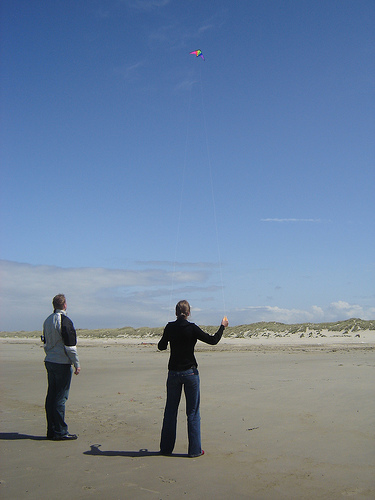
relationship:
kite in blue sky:
[190, 48, 207, 63] [0, 0, 375, 328]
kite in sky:
[189, 49, 205, 62] [105, 70, 221, 176]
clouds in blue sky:
[0, 258, 373, 332] [0, 0, 375, 328]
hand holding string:
[214, 313, 233, 329] [193, 68, 253, 242]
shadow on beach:
[83, 441, 163, 459] [1, 337, 373, 497]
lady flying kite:
[155, 296, 231, 459] [191, 41, 208, 59]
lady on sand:
[155, 296, 231, 459] [254, 362, 350, 462]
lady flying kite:
[155, 296, 231, 459] [185, 40, 206, 67]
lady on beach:
[155, 296, 231, 459] [1, 337, 373, 497]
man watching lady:
[40, 294, 81, 439] [155, 296, 231, 459]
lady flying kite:
[155, 296, 231, 459] [187, 46, 207, 64]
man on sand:
[40, 294, 81, 439] [1, 332, 372, 499]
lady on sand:
[155, 296, 231, 459] [1, 332, 372, 499]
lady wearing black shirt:
[158, 300, 229, 456] [153, 320, 225, 370]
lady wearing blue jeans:
[158, 300, 229, 456] [158, 368, 203, 456]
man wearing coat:
[34, 289, 80, 442] [38, 311, 81, 367]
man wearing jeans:
[34, 289, 80, 442] [40, 363, 73, 441]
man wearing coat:
[40, 294, 81, 439] [39, 307, 80, 366]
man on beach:
[40, 294, 81, 439] [1, 337, 373, 497]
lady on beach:
[158, 300, 229, 456] [1, 337, 373, 497]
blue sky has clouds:
[0, 0, 375, 328] [0, 253, 373, 323]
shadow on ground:
[83, 444, 188, 457] [2, 343, 373, 497]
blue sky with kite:
[248, 55, 344, 199] [189, 48, 208, 62]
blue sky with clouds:
[0, 0, 375, 328] [0, 258, 373, 332]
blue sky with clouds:
[0, 0, 375, 328] [256, 215, 322, 224]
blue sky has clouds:
[0, 0, 375, 328] [2, 10, 370, 331]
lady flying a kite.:
[158, 300, 229, 456] [133, 24, 241, 95]